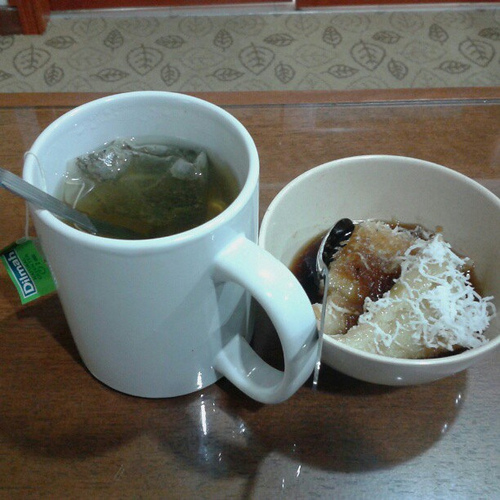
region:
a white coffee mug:
[11, 82, 326, 436]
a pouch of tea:
[66, 138, 206, 245]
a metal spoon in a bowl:
[298, 199, 355, 398]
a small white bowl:
[243, 123, 498, 400]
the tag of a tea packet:
[1, 234, 63, 314]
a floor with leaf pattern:
[2, 6, 499, 92]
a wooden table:
[1, 80, 497, 494]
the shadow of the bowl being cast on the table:
[233, 318, 486, 484]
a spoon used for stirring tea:
[1, 150, 171, 246]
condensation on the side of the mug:
[65, 98, 214, 141]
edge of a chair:
[216, 207, 246, 232]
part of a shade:
[338, 418, 369, 449]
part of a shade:
[334, 416, 374, 468]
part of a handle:
[268, 288, 296, 349]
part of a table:
[348, 388, 392, 428]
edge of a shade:
[371, 456, 391, 468]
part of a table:
[388, 439, 431, 478]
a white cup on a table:
[20, 90, 316, 405]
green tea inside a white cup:
[25, 87, 260, 239]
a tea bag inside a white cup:
[72, 143, 207, 230]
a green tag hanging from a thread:
[0, 237, 60, 305]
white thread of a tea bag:
[17, 150, 48, 235]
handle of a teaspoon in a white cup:
[0, 167, 142, 234]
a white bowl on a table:
[261, 153, 496, 388]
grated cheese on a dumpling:
[317, 216, 497, 353]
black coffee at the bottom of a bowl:
[290, 211, 485, 366]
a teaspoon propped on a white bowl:
[306, 219, 356, 389]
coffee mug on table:
[13, 70, 370, 470]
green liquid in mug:
[65, 141, 255, 278]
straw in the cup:
[3, 158, 145, 267]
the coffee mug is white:
[18, 73, 338, 433]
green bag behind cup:
[5, 221, 89, 351]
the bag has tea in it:
[11, 232, 73, 319]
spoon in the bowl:
[293, 186, 375, 449]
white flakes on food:
[386, 236, 497, 358]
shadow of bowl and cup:
[23, 327, 486, 472]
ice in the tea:
[68, 120, 226, 227]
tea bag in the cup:
[26, 114, 259, 293]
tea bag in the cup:
[47, 129, 200, 234]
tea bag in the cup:
[47, 129, 282, 414]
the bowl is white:
[277, 151, 494, 418]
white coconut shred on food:
[315, 203, 497, 371]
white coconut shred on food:
[319, 237, 432, 331]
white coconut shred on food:
[345, 215, 470, 330]